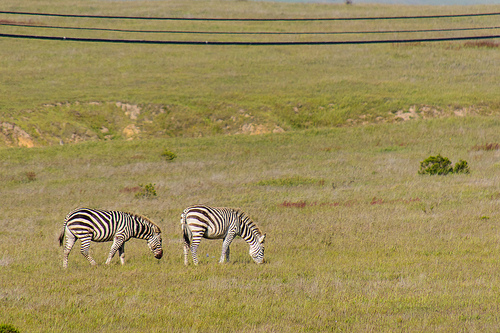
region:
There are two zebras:
[35, 200, 281, 309]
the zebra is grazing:
[169, 175, 324, 297]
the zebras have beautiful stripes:
[56, 189, 286, 301]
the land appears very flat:
[10, 125, 497, 330]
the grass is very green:
[16, 136, 476, 198]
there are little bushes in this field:
[418, 147, 473, 191]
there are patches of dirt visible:
[3, 91, 316, 153]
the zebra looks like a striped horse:
[47, 200, 173, 284]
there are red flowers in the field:
[273, 198, 405, 211]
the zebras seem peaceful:
[47, 194, 310, 283]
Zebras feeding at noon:
[51, 196, 272, 276]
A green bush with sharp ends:
[410, 145, 475, 181]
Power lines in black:
[136, 11, 476, 54]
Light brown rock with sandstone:
[230, 110, 290, 141]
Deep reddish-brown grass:
[280, 195, 310, 210]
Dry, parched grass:
[362, 275, 424, 290]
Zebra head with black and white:
[248, 227, 268, 270]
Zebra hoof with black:
[52, 262, 73, 267]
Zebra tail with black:
[55, 220, 65, 246]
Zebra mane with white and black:
[232, 209, 262, 236]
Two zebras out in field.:
[2, 79, 395, 294]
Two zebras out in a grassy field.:
[36, 111, 357, 295]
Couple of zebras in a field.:
[5, 76, 363, 285]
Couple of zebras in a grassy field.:
[33, 102, 387, 298]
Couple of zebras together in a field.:
[25, 102, 387, 293]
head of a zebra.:
[140, 214, 175, 264]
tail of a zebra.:
[173, 206, 200, 250]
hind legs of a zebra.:
[57, 241, 98, 264]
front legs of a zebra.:
[99, 244, 133, 268]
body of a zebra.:
[192, 201, 236, 238]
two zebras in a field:
[23, 169, 410, 314]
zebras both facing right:
[31, 182, 286, 284]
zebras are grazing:
[48, 197, 270, 274]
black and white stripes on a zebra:
[61, 205, 156, 250]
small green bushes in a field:
[417, 149, 470, 179]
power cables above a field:
[0, 4, 499, 69]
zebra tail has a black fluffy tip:
[177, 211, 192, 253]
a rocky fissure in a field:
[4, 92, 481, 167]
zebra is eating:
[177, 198, 269, 273]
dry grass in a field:
[1, 55, 498, 331]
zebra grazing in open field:
[178, 202, 267, 267]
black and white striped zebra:
[56, 205, 165, 267]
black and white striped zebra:
[176, 203, 266, 266]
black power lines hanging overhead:
[0, 7, 498, 44]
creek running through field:
[3, 97, 499, 149]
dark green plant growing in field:
[418, 155, 468, 178]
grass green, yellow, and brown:
[1, 0, 499, 330]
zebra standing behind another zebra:
[56, 206, 165, 271]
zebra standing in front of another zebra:
[176, 205, 267, 266]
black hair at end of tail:
[179, 231, 194, 248]